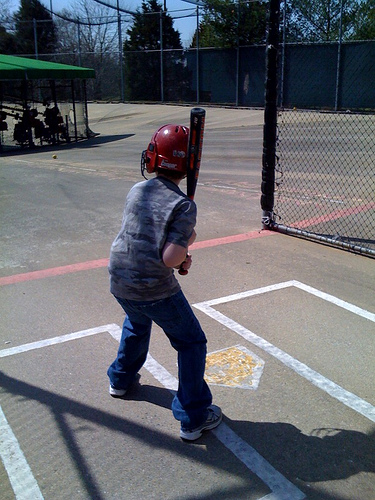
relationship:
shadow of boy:
[127, 374, 374, 485] [104, 125, 222, 443]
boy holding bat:
[104, 125, 222, 443] [178, 108, 206, 275]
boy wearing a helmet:
[104, 125, 222, 443] [140, 124, 186, 180]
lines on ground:
[0, 323, 303, 498] [1, 102, 372, 499]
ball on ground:
[50, 152, 58, 159] [1, 102, 372, 499]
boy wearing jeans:
[104, 125, 222, 443] [107, 287, 212, 431]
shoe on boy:
[177, 404, 226, 442] [104, 125, 222, 443]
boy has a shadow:
[104, 125, 222, 443] [127, 374, 374, 485]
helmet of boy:
[140, 124, 186, 180] [104, 125, 222, 443]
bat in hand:
[178, 108, 206, 275] [179, 251, 192, 273]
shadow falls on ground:
[127, 374, 374, 485] [1, 102, 372, 499]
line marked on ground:
[1, 204, 366, 285] [1, 102, 372, 499]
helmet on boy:
[140, 124, 186, 180] [104, 125, 222, 443]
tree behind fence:
[125, 0, 184, 103] [0, 2, 375, 113]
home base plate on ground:
[203, 345, 266, 391] [1, 102, 372, 499]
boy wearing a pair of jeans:
[104, 125, 222, 443] [107, 287, 212, 431]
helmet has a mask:
[140, 124, 186, 180] [140, 152, 155, 180]